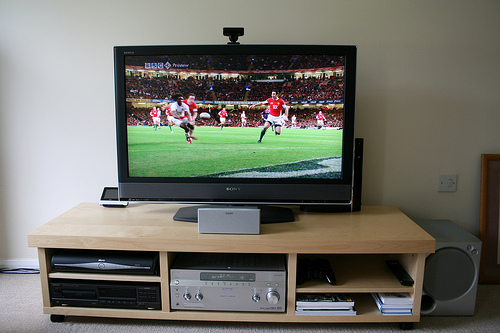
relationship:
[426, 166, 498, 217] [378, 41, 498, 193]
socket on wall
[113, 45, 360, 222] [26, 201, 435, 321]
television on entertainment center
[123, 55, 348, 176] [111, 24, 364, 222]
soccer match on television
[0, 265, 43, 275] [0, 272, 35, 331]
power cords on floor